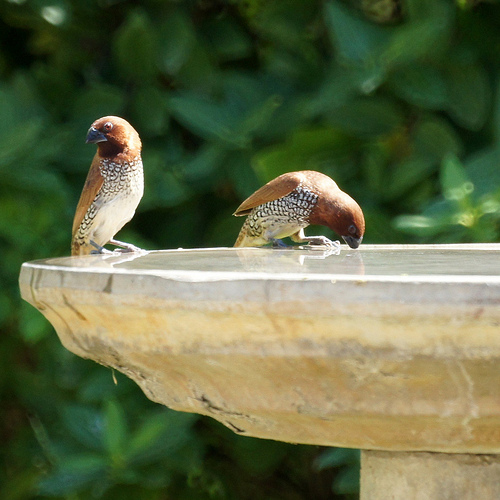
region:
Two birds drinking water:
[40, 62, 476, 483]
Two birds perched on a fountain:
[59, 81, 405, 301]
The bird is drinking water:
[224, 152, 388, 271]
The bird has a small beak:
[78, 122, 108, 152]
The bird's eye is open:
[100, 117, 121, 134]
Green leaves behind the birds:
[148, 35, 409, 158]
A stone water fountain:
[42, 241, 476, 451]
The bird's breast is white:
[98, 201, 145, 246]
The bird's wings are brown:
[239, 173, 309, 213]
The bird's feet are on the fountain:
[292, 235, 336, 255]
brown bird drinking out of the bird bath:
[216, 161, 376, 263]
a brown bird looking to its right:
[65, 110, 150, 250]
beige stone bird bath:
[13, 239, 428, 478]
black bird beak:
[84, 121, 104, 149]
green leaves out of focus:
[165, 53, 416, 164]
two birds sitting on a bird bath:
[69, 90, 389, 268]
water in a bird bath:
[349, 253, 441, 281]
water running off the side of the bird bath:
[26, 263, 97, 330]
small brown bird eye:
[100, 119, 116, 134]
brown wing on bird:
[226, 176, 304, 211]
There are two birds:
[62, 110, 383, 270]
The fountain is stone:
[27, 227, 491, 489]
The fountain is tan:
[47, 206, 485, 489]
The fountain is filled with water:
[11, 216, 492, 404]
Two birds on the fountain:
[36, 110, 386, 274]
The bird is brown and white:
[58, 110, 168, 264]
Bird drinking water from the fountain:
[219, 151, 392, 265]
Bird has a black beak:
[57, 117, 161, 170]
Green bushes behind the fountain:
[22, 106, 497, 476]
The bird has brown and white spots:
[221, 161, 353, 275]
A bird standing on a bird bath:
[70, 113, 145, 257]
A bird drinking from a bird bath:
[234, 168, 366, 249]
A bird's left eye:
[102, 121, 112, 132]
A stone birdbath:
[17, 241, 498, 499]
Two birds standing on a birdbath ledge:
[18, 112, 496, 499]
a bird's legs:
[90, 238, 145, 255]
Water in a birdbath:
[44, 249, 496, 276]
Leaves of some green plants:
[1, 2, 498, 499]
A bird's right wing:
[228, 176, 299, 218]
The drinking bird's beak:
[345, 229, 363, 244]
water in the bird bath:
[171, 229, 371, 294]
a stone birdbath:
[27, 155, 485, 497]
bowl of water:
[26, 207, 498, 473]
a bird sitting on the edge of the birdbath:
[52, 102, 183, 286]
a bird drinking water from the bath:
[229, 132, 414, 286]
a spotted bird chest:
[90, 147, 143, 189]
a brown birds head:
[81, 103, 131, 169]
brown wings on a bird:
[51, 140, 126, 257]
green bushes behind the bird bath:
[210, 77, 402, 140]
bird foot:
[300, 230, 353, 255]